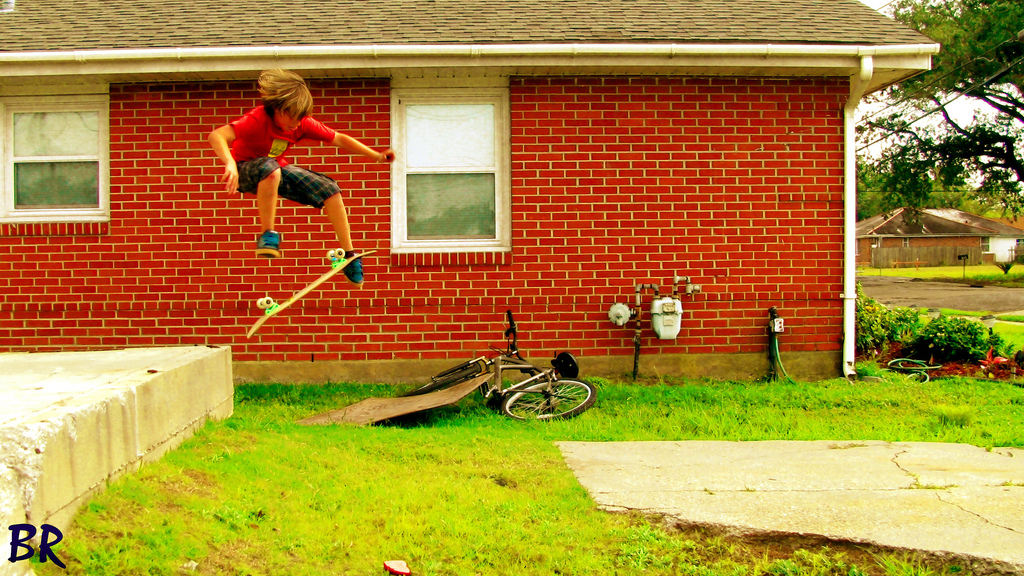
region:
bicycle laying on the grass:
[417, 304, 592, 448]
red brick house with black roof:
[6, 6, 873, 374]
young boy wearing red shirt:
[192, 51, 390, 277]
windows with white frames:
[4, 90, 523, 259]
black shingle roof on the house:
[4, 7, 940, 45]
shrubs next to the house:
[857, 270, 1007, 372]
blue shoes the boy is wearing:
[246, 235, 374, 287]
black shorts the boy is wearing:
[237, 168, 342, 210]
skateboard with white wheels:
[237, 247, 375, 350]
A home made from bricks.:
[0, 0, 939, 384]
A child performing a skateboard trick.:
[206, 66, 399, 339]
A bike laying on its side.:
[400, 307, 597, 421]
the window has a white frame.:
[389, 86, 511, 252]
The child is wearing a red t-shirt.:
[204, 66, 394, 289]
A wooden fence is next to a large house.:
[858, 206, 1021, 267]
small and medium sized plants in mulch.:
[854, 279, 1022, 381]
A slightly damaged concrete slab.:
[0, 344, 234, 573]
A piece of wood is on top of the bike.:
[292, 309, 599, 426]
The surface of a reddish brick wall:
[578, 126, 715, 185]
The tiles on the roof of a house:
[224, 1, 468, 30]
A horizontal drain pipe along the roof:
[265, 49, 437, 54]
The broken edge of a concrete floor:
[724, 524, 798, 537]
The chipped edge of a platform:
[2, 447, 32, 492]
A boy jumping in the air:
[205, 71, 370, 259]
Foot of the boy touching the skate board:
[325, 243, 368, 285]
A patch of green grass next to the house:
[638, 387, 769, 404]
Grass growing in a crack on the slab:
[909, 485, 942, 489]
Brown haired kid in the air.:
[208, 71, 393, 284]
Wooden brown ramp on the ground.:
[299, 369, 496, 428]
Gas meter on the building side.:
[647, 296, 683, 339]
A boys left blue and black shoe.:
[332, 251, 365, 289]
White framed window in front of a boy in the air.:
[387, 72, 514, 254]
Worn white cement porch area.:
[3, 350, 235, 553]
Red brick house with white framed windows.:
[3, 2, 939, 385]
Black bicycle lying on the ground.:
[403, 312, 596, 424]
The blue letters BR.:
[9, 523, 66, 566]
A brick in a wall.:
[645, 248, 672, 264]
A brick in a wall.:
[599, 235, 618, 246]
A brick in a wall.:
[615, 177, 636, 190]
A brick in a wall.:
[635, 137, 664, 157]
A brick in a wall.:
[673, 108, 703, 129]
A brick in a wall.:
[771, 210, 803, 221]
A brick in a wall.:
[591, 213, 618, 224]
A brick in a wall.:
[204, 263, 228, 273]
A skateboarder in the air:
[179, 36, 430, 366]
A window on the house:
[365, 58, 527, 265]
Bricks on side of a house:
[0, 65, 851, 369]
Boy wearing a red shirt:
[197, 51, 356, 166]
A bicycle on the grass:
[408, 289, 608, 441]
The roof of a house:
[0, 0, 939, 77]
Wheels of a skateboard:
[235, 276, 289, 319]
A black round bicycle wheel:
[481, 358, 606, 434]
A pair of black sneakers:
[238, 206, 374, 301]